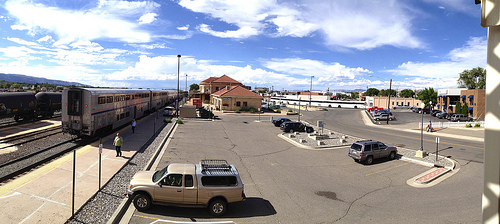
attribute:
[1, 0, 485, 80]
sky — clear, clouds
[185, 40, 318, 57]
sky — clear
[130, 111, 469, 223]
street — large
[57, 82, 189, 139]
train — silver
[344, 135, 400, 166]
truck — silver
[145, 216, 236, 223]
line — white,  white